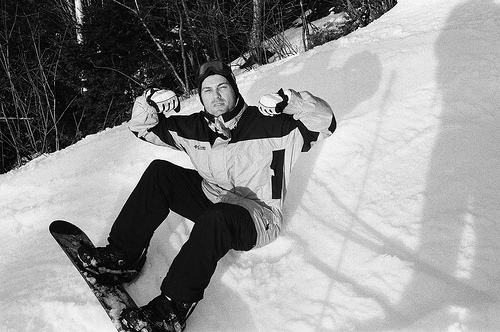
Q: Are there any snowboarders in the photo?
A: Yes, there is a snowboarder.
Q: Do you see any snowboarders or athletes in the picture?
A: Yes, there is a snowboarder.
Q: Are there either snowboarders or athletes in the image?
A: Yes, there is a snowboarder.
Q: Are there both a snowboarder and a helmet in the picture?
A: No, there is a snowboarder but no helmets.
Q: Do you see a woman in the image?
A: No, there are no women.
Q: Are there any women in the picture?
A: No, there are no women.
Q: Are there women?
A: No, there are no women.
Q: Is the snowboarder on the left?
A: Yes, the snowboarder is on the left of the image.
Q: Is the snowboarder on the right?
A: No, the snowboarder is on the left of the image.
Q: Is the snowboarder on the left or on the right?
A: The snowboarder is on the left of the image.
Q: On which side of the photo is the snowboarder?
A: The snowboarder is on the left of the image.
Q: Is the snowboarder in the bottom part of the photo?
A: Yes, the snowboarder is in the bottom of the image.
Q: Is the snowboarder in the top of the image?
A: No, the snowboarder is in the bottom of the image.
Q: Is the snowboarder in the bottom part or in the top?
A: The snowboarder is in the bottom of the image.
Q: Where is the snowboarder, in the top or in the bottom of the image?
A: The snowboarder is in the bottom of the image.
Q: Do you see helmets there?
A: No, there are no helmets.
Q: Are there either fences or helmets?
A: No, there are no helmets or fences.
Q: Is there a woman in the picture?
A: No, there are no women.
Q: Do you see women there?
A: No, there are no women.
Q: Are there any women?
A: No, there are no women.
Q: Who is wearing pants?
A: The man is wearing pants.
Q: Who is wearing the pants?
A: The man is wearing pants.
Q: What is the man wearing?
A: The man is wearing trousers.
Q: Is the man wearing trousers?
A: Yes, the man is wearing trousers.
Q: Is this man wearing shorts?
A: No, the man is wearing trousers.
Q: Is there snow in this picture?
A: Yes, there is snow.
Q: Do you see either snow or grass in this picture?
A: Yes, there is snow.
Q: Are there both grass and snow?
A: No, there is snow but no grass.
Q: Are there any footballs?
A: No, there are no footballs.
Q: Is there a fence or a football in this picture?
A: No, there are no footballs or fences.